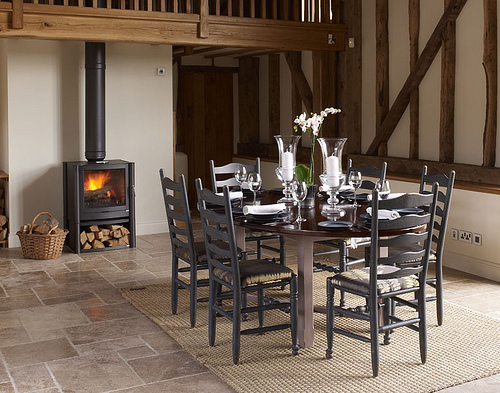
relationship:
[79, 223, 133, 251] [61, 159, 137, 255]
wood under stove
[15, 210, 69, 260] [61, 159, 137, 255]
basket near stove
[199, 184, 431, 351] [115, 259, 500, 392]
table on rug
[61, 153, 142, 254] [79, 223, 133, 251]
stove burning wood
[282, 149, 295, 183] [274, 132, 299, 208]
candle in holder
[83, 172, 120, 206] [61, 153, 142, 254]
fire in wood stove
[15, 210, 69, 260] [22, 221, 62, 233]
basket with logs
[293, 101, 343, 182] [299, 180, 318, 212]
flower in vase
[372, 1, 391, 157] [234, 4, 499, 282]
wood on wall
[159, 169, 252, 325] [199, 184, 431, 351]
chair by table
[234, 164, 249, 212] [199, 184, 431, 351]
glass on table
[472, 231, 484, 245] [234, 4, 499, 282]
socket on wall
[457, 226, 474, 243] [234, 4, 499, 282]
socket on wall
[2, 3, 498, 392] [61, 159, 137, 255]
room with stove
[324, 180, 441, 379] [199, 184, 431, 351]
chair by table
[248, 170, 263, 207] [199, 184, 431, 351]
glass on table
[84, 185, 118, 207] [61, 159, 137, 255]
wood in stove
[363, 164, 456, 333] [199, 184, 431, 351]
chair by table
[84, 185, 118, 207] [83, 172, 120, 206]
logs under fire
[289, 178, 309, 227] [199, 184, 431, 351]
glass on table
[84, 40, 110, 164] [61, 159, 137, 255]
stove pipe above stove